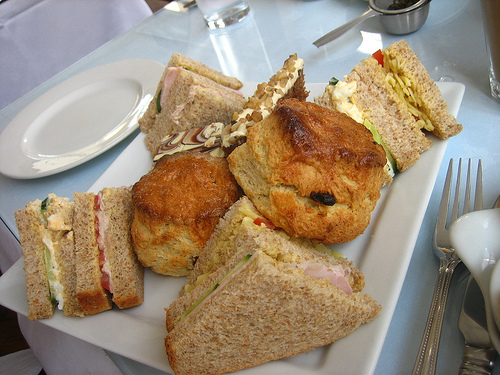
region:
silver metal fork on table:
[406, 155, 486, 371]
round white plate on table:
[0, 52, 175, 177]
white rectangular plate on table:
[1, 70, 468, 373]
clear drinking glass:
[186, 0, 252, 32]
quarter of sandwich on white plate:
[156, 193, 385, 373]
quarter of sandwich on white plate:
[10, 184, 148, 324]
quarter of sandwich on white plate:
[309, 37, 466, 177]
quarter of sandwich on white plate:
[135, 51, 256, 168]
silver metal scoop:
[306, 0, 434, 55]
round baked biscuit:
[224, 93, 394, 248]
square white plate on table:
[1, 80, 464, 371]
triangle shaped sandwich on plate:
[12, 190, 82, 320]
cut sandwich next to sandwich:
[70, 186, 141, 311]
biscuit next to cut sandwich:
[130, 150, 240, 275]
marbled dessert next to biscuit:
[150, 117, 225, 157]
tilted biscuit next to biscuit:
[225, 97, 390, 239]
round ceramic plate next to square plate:
[0, 55, 155, 175]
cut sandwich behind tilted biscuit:
[315, 66, 420, 176]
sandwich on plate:
[350, 36, 462, 151]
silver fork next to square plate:
[412, 155, 479, 371]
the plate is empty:
[8, 114, 132, 171]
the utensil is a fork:
[414, 159, 467, 371]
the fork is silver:
[414, 152, 478, 370]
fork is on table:
[414, 152, 482, 373]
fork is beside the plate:
[369, 137, 465, 366]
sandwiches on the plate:
[182, 205, 404, 372]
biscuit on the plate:
[227, 110, 401, 242]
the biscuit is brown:
[234, 107, 393, 254]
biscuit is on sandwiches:
[221, 104, 391, 294]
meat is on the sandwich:
[253, 219, 363, 321]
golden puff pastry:
[224, 95, 402, 250]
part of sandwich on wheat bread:
[11, 187, 147, 326]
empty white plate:
[3, 55, 155, 180]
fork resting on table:
[403, 148, 498, 370]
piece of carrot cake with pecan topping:
[220, 53, 304, 148]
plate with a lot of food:
[15, 44, 450, 374]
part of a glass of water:
[192, 0, 252, 32]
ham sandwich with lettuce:
[160, 194, 382, 374]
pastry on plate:
[106, 149, 281, 276]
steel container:
[307, 2, 447, 56]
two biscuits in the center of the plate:
[133, 100, 384, 271]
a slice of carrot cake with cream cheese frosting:
[226, 54, 307, 150]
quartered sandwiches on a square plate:
[23, 45, 463, 350]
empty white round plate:
[5, 59, 157, 174]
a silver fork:
[412, 155, 482, 373]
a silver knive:
[461, 280, 496, 373]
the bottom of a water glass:
[197, 1, 245, 28]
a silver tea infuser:
[317, 2, 429, 40]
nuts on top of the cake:
[224, 58, 297, 148]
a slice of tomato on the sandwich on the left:
[92, 190, 107, 283]